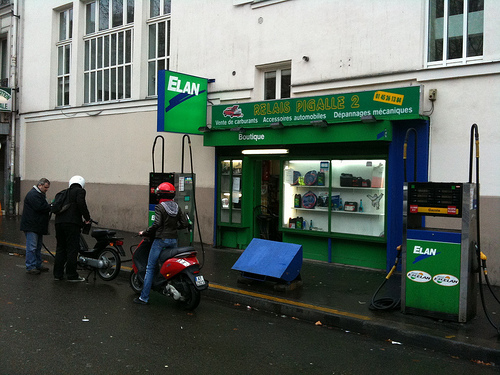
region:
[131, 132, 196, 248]
The gas pump to the left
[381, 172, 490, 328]
The gas pump to the right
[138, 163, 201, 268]
A gas pump to the left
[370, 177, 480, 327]
A gas pump to the right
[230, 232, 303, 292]
The blue item in the middle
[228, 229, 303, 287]
The blue item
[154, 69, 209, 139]
The green store sign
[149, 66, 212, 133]
A green store sign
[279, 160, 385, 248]
The display window in the front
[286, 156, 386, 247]
A display window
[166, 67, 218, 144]
a green sign on building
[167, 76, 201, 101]
white lettering on sign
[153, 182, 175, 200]
a helmet is red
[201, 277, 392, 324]
a yellow line on the sidewalk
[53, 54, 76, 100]
a window on the building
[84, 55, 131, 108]
a window on the building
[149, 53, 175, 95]
a window on the building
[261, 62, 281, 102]
a window on the building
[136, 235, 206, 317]
a red motorcycle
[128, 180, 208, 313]
the person on the scooter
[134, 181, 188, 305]
the person is wearing a helmet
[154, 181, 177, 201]
the helmet is red and black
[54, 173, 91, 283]
the person wearing a helmet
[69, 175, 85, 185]
the helmet is white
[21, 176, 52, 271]
the standing man has gray hair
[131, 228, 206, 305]
the scooter is red and black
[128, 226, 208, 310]
the seat on the scooter is black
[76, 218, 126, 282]
the scooter is black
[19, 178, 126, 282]
the men standing near the black scooter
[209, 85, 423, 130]
language on the sign is French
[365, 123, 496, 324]
gasoline pump at the edge of a street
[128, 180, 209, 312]
motorcyclist on a red motorbike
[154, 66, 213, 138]
shop sign announcing the shop's name Elan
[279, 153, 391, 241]
items in shop window for sale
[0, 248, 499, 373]
street beside the gas pump is wet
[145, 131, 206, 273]
gasoline pump by the side of the road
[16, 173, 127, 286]
two guys filling up the tank of a motorbike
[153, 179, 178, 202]
motorcyclist's helmet is red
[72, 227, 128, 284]
motorbike is black with silver detailing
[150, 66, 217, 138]
green and white sign on side of building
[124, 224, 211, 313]
red motorcycle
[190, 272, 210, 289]
license plate on back of motorcycle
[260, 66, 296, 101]
window on side of building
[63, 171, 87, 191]
white helmet on person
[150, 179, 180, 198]
red helmet on person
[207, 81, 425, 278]
green store front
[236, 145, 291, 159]
long white light over doorway of store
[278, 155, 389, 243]
glass display case with white shelves on store front